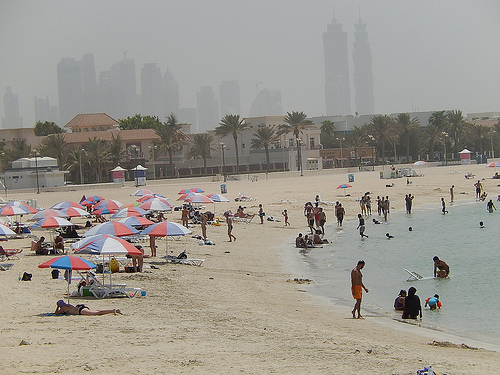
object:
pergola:
[131, 164, 148, 185]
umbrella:
[70, 233, 143, 255]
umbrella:
[28, 216, 74, 228]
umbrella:
[139, 198, 173, 211]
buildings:
[34, 51, 195, 136]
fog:
[0, 1, 500, 133]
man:
[349, 260, 369, 319]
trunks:
[353, 270, 363, 286]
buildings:
[249, 85, 284, 117]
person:
[440, 198, 448, 215]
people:
[430, 254, 452, 279]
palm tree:
[215, 115, 254, 173]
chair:
[405, 268, 424, 282]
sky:
[0, 0, 499, 133]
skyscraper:
[321, 0, 349, 118]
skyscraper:
[350, 5, 374, 115]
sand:
[427, 340, 485, 350]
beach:
[0, 160, 500, 374]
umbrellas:
[1, 204, 30, 215]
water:
[302, 196, 499, 343]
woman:
[53, 300, 123, 316]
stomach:
[69, 307, 76, 315]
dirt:
[119, 272, 414, 372]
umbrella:
[35, 252, 100, 296]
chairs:
[73, 270, 144, 299]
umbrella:
[140, 219, 191, 236]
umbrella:
[184, 193, 213, 203]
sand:
[286, 277, 315, 285]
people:
[336, 203, 346, 226]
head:
[479, 221, 484, 226]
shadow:
[32, 312, 70, 317]